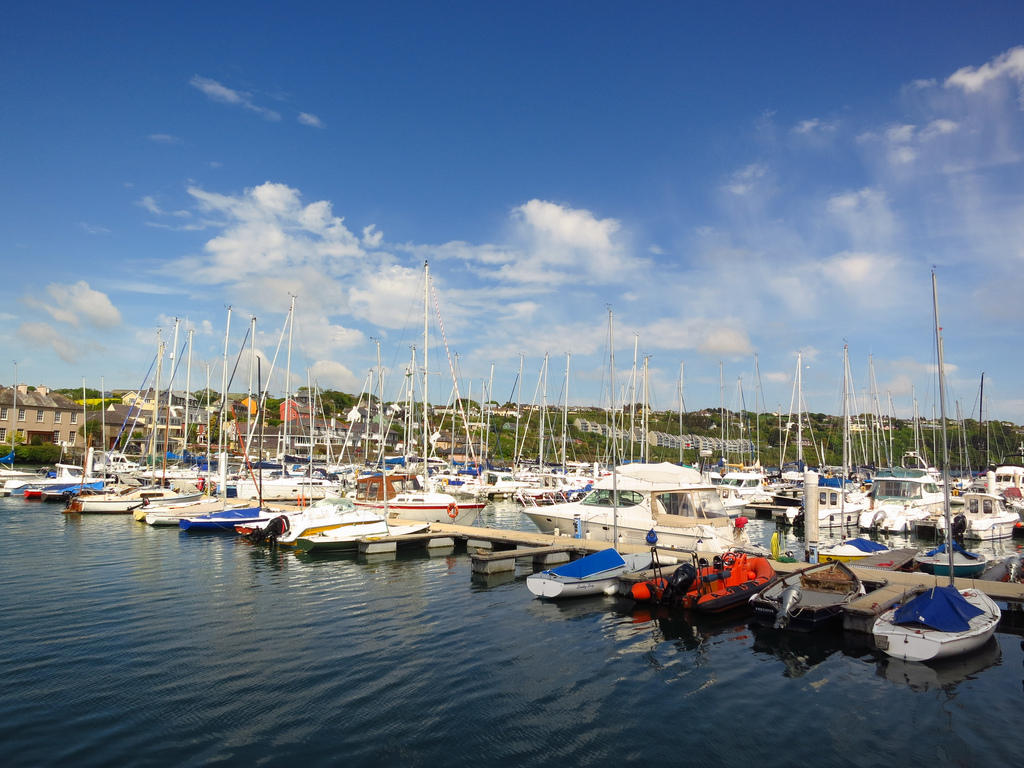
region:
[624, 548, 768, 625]
Orange boat docked to a pier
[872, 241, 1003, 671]
White sailboat docked to a pier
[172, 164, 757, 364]
White clouds in a blue sky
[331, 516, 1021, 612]
Wood pier on a lake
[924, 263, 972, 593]
Mast on a sailboat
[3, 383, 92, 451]
Building near a harbor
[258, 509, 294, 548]
Outboard motor on a boat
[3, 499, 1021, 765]
Water at a harbor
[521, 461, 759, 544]
Motor boat tied to a dock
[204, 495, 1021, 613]
a long dock at a marina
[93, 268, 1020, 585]
masts of many small sailboats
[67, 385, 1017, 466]
distant tree-covered hills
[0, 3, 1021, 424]
a blue sky with a few clouds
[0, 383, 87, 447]
a light brown building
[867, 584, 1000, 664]
a small white sailboat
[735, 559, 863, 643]
a small black sailboat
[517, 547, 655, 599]
a small white boat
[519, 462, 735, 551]
a larger white boat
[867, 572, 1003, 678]
a blue and white boat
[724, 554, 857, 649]
a grey boat at a dock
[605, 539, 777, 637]
a red boat at a dock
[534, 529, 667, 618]
a white boat with a blue tarp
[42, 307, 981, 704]
a group of sailboats at a dock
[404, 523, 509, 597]
an empty slot at the dock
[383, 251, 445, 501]
a tall wooden mast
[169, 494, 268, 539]
a small blue boat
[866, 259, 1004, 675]
Sailboat tied to a dock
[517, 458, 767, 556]
Motor boat tied to a pier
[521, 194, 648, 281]
white cloud in the sky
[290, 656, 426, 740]
water is blue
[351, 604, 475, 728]
the blue water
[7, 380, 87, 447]
a house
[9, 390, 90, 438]
the house is brown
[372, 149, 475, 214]
the sky is clear and blue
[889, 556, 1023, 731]
a boat in the water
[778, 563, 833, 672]
a boat in the water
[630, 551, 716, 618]
a boat in the water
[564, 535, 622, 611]
a boat in the water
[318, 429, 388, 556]
a boat in the water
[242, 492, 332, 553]
a boat in the water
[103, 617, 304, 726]
Large body of water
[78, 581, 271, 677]
Large body of water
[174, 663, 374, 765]
Large body of water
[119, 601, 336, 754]
Large body of water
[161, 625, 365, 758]
Large body of water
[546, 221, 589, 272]
a white fluffy cloud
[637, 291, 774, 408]
a white fluffy cloud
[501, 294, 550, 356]
a white fluffy cloud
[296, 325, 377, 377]
a white fluffy cloud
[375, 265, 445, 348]
a white fluffy cloud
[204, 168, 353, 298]
a white fluffy cloud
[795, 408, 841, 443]
green leaves on the tree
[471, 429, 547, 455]
green leaves on the tree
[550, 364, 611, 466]
green leaves on the tree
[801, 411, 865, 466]
green leaves on the tree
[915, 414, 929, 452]
green leaves on the tree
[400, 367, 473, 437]
green leaves on the tree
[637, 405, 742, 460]
green leaves on the tree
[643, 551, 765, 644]
a red boat in water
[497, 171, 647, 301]
white cloud in sky